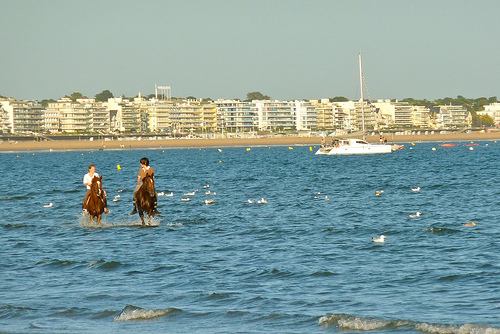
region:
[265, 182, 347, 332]
the water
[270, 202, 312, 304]
the water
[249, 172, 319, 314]
the water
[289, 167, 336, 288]
the water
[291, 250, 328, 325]
the water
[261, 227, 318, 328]
the water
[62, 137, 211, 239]
two horse in water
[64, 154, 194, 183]
two person in water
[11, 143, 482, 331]
a beautiful view of water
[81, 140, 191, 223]
two horses and two persons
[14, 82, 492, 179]
a big group of buildings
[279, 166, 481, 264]
birds present on water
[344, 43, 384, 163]
a long pillar on road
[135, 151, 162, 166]
hairs of the person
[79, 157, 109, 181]
face of the person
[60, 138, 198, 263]
two horse running in water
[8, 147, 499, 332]
large blue body of water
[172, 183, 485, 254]
birds on surface of water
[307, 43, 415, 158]
small boat on the water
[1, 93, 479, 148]
wall of buildings of similar heights near the beach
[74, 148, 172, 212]
two people on horses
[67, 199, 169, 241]
horses kicking up spray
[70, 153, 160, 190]
one rider looking towards the other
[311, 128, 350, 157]
people on boat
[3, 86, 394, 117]
tree tops visible behind buildings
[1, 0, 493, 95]
sky is a hazy blue color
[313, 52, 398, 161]
yatch out in the water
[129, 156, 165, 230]
brown horse running through the water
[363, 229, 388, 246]
white duck floating on top of water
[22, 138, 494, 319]
blue waters and some white waves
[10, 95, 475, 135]
group of buildings on shore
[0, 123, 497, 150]
sand on shore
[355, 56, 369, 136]
tall mask of a white boat in water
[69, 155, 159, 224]
two people on horses in the water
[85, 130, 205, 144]
group of seagulls on the beach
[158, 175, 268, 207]
bunch of ducks in the water